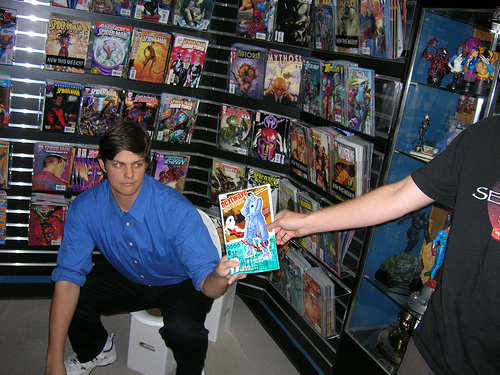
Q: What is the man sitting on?
A: Toilet.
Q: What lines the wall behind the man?
A: Comic books.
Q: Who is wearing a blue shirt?
A: The man on the toilet.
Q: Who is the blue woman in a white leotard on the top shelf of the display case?
A: Mystique.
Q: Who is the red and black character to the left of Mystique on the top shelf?
A: Venom.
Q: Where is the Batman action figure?
A: On the second shelf.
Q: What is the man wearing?
A: Black pants.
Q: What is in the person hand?
A: Comic Book.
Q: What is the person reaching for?
A: Magazine.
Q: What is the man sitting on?
A: Toilet.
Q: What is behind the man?
A: Rack of comic books.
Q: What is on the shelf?
A: Figurines.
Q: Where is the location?
A: Store.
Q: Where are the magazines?
A: On display.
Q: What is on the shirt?
A: Buttons.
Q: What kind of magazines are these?
A: Comic books.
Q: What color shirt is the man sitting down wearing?
A: Blue.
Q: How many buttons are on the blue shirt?
A: Five.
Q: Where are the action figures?
A: In the showcase.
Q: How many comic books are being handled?
A: One.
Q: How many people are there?
A: Two.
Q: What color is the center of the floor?
A: Tan.